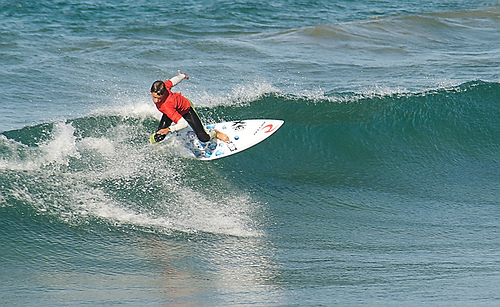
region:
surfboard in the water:
[221, 118, 276, 155]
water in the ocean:
[229, 179, 400, 271]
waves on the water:
[27, 163, 159, 237]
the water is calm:
[278, 30, 389, 63]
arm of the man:
[165, 75, 184, 89]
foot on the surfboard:
[212, 129, 236, 143]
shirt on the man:
[167, 94, 187, 111]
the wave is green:
[320, 142, 435, 188]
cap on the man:
[148, 84, 166, 94]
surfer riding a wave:
[135, 73, 287, 163]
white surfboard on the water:
[171, 112, 288, 162]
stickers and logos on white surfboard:
[168, 118, 280, 158]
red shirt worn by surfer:
[158, 79, 193, 119]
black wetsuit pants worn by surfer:
[145, 117, 208, 147]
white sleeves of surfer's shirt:
[165, 70, 193, 131]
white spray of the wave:
[20, 64, 466, 229]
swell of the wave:
[19, 124, 491, 221]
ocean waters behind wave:
[8, 4, 498, 78]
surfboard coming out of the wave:
[160, 109, 295, 161]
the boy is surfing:
[131, 69, 289, 185]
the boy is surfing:
[121, 57, 318, 202]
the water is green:
[344, 128, 442, 224]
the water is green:
[299, 134, 391, 216]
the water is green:
[327, 119, 441, 208]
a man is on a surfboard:
[143, 69, 286, 161]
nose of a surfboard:
[215, 116, 284, 150]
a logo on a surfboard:
[230, 120, 246, 131]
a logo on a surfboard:
[252, 118, 279, 143]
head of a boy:
[149, 79, 167, 104]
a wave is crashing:
[3, 114, 263, 236]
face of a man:
[151, 91, 163, 105]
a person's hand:
[155, 126, 170, 137]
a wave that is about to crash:
[260, 79, 498, 214]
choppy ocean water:
[0, 1, 499, 121]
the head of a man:
[144, 75, 176, 108]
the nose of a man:
[139, 86, 164, 112]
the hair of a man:
[141, 77, 186, 114]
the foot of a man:
[213, 120, 241, 153]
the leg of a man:
[174, 97, 226, 165]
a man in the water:
[121, 50, 250, 178]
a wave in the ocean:
[120, 22, 355, 239]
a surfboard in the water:
[119, 42, 299, 213]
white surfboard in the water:
[145, 110, 288, 158]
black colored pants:
[148, 105, 218, 152]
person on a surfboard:
[138, 65, 232, 154]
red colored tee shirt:
[153, 78, 193, 123]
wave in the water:
[6, 74, 497, 209]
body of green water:
[2, 1, 499, 302]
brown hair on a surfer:
[151, 78, 165, 92]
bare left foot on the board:
[214, 127, 230, 144]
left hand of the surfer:
[153, 125, 170, 141]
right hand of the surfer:
[176, 67, 191, 80]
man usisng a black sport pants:
[156, 81, 206, 146]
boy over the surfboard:
[141, 78, 252, 158]